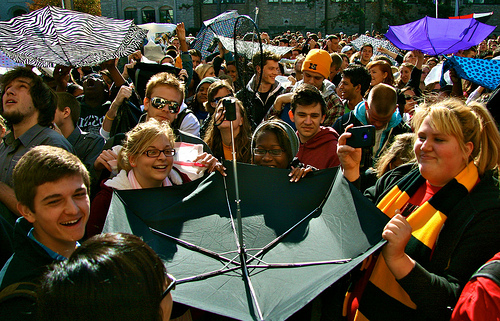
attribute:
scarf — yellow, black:
[372, 154, 492, 304]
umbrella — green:
[106, 145, 396, 319]